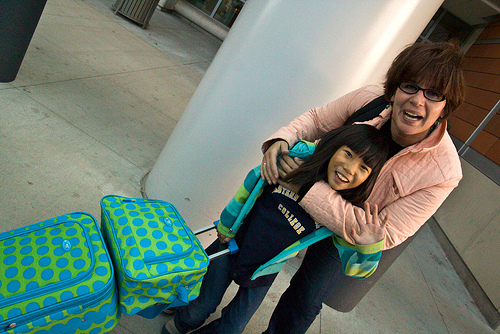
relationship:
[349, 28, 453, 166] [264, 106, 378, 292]
woman hugging girl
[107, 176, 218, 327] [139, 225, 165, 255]
bag has dots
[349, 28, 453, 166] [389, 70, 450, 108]
woman with eyeglasses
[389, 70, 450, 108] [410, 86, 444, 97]
eyeglasses has frame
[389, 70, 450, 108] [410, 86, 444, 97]
eyeglasses have frame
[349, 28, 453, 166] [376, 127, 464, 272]
woman wearing jacket